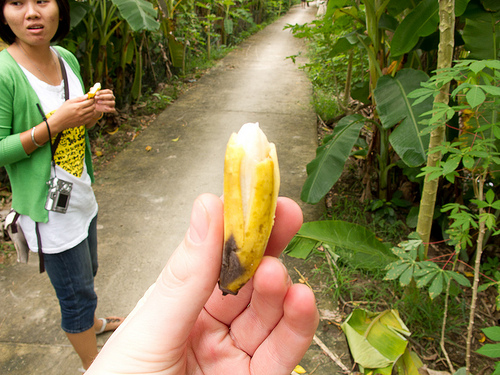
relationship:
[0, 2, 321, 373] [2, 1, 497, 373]
path through banana grove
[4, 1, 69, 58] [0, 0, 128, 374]
head of woman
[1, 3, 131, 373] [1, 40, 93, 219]
woman in cardigan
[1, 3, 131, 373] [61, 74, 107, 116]
woman with banana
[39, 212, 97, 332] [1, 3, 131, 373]
jeans on woman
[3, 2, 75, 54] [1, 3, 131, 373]
black hair on woman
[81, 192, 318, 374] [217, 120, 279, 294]
person holding banana